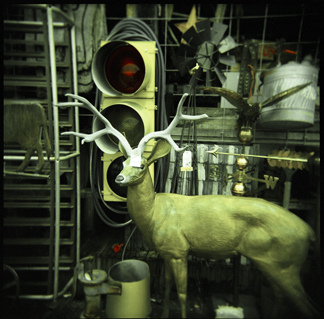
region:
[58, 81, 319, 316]
STATUE OF STANDING DEER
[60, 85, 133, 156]
ANTLER OF STANDING DEER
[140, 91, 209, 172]
ABTLER OF STANDING DEER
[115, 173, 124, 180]
NOSE OF STANDING DEER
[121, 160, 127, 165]
EYE OF STANDING DEER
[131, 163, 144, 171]
EYE OF STANDING DEER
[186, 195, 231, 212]
BACK OF STANDING DEER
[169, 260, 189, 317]
LEG OF STANDING DEER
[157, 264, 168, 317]
LEG OF STANDING DEER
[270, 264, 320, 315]
LEG OF STANDING DEER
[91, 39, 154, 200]
stop light behind deer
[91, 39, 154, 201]
no lights are shining on stoplight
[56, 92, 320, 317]
fake deer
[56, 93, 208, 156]
deer has white antlers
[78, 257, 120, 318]
water pump with rust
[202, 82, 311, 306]
metal weather vane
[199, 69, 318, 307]
weather vane has metal eagle on top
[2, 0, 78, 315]
metal rack to side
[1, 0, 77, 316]
metal rack has wheels on it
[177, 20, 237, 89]
metal windmill behind other metal objects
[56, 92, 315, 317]
the deer is fake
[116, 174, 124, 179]
the nose is black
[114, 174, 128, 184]
snout of a deer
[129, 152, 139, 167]
the tag is white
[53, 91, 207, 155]
the antlers are white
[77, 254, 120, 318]
an old piece of metal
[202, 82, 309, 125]
statue of an eagle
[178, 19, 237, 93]
a metal wind mill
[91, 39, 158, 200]
a set of traffic lights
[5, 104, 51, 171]
part of a cow image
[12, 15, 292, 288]
this is a garage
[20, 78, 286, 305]
this is a storage area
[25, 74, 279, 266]
this area is cluttered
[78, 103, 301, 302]
this is a fake deer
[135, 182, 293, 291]
the deer is light brown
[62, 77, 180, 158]
the deers antlers are gray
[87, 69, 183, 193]
this is a traffic signal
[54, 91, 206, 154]
antlers on a deer statue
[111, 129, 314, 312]
a deer statue for sale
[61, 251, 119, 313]
possibly part of a pump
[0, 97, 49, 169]
half of a cow figurine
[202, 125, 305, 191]
a gold colored weather vane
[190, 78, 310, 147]
the bird that is on top of the weathervane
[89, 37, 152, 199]
large yellow traffic light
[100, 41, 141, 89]
top red light on traffic light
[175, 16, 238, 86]
top part of a metal windmill